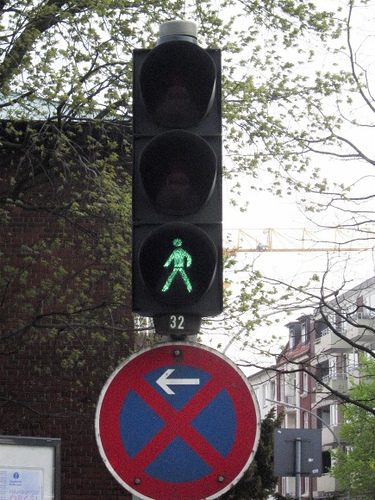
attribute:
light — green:
[150, 231, 205, 303]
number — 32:
[165, 312, 190, 340]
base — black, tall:
[132, 49, 220, 337]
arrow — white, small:
[154, 365, 202, 395]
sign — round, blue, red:
[94, 340, 260, 499]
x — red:
[127, 373, 227, 474]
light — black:
[129, 47, 223, 337]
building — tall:
[278, 277, 375, 484]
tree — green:
[1, 2, 131, 350]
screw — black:
[172, 349, 181, 359]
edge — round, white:
[91, 367, 109, 479]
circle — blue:
[121, 365, 235, 485]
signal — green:
[128, 217, 222, 318]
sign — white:
[1, 436, 64, 499]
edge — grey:
[52, 439, 64, 500]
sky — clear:
[225, 205, 302, 243]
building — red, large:
[3, 117, 95, 436]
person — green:
[160, 230, 194, 294]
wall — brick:
[4, 119, 133, 359]